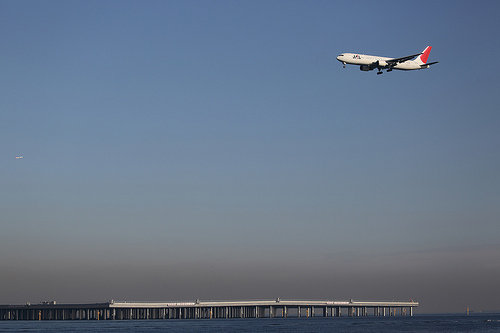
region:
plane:
[329, 24, 440, 89]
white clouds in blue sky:
[35, 78, 90, 120]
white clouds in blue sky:
[67, 101, 109, 147]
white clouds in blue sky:
[93, 200, 120, 217]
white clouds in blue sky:
[202, 161, 251, 203]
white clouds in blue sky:
[298, 167, 331, 218]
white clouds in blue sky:
[342, 204, 389, 233]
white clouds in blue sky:
[157, 84, 210, 136]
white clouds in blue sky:
[223, 114, 263, 177]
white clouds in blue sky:
[95, 158, 143, 220]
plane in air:
[328, 38, 450, 80]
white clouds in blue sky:
[27, 3, 67, 48]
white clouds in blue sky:
[157, 128, 221, 163]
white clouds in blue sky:
[232, 142, 257, 180]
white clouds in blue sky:
[298, 162, 328, 197]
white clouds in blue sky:
[380, 156, 447, 228]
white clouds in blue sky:
[45, 176, 90, 217]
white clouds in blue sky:
[114, 123, 201, 214]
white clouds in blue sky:
[157, 56, 201, 114]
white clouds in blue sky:
[227, 148, 269, 200]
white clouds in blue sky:
[50, 13, 111, 63]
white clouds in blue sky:
[161, 135, 205, 175]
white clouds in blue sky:
[70, 143, 145, 173]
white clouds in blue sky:
[228, 198, 288, 245]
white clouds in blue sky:
[397, 176, 447, 214]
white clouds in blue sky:
[25, 169, 75, 240]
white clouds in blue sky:
[164, 93, 245, 134]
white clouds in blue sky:
[212, 181, 253, 216]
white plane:
[318, 29, 440, 87]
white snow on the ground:
[107, 155, 147, 180]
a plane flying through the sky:
[325, 29, 447, 89]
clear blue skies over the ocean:
[67, 72, 287, 205]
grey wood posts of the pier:
[95, 309, 277, 317]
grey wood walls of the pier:
[101, 296, 275, 311]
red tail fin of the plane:
[414, 43, 441, 70]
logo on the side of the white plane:
[351, 54, 363, 63]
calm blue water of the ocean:
[343, 315, 443, 331]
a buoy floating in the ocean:
[463, 305, 472, 316]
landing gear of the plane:
[335, 63, 397, 79]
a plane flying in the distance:
[11, 152, 30, 165]